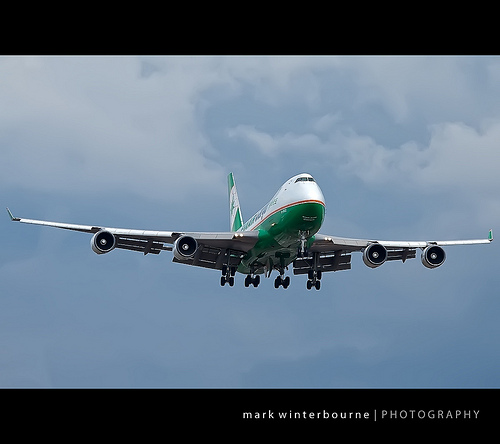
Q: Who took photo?
A: Professional.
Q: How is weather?
A: Cloudy.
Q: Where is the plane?
A: In the sky.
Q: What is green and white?
A: The plane.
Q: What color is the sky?
A: Blue.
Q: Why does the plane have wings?
A: To fly.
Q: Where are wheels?
A: On the bottom of the plane.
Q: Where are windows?
A: On the plane.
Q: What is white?
A: Clouds.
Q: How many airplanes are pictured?
A: One.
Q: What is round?
A: Wheels.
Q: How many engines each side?
A: 2.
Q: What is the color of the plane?
A: Green and white.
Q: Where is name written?
A: Right bottom.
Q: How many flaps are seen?
A: 4.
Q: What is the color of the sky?
A: Blue.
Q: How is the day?
A: Sunny.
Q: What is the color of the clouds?
A: White.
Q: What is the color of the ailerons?
A: White.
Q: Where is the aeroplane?
A: In the sky.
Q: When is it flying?
A: During the day.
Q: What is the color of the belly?
A: It is green.